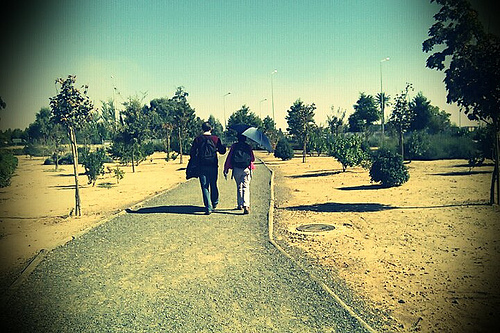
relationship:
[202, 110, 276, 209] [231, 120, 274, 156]
person with umbrella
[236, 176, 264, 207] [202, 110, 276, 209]
leg of person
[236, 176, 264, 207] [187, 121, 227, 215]
leg of man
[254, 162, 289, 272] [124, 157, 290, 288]
edge of path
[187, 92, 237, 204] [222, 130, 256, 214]
man and person